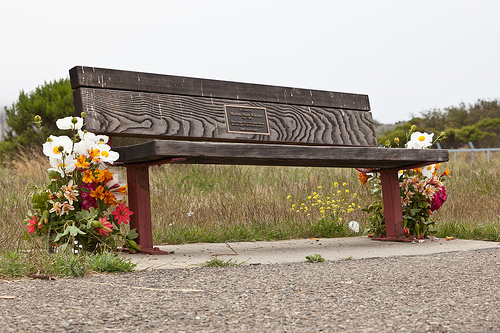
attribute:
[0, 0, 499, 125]
sky — clear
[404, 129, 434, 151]
flower — white, yellow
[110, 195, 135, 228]
flower — red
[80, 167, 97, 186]
flower — orange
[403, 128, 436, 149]
flower — yellow, white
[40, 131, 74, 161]
flower — white, yellow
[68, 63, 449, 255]
bench — vacant, wooden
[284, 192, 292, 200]
flower — yellow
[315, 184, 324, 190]
flower — yellow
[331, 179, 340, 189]
flower — yellow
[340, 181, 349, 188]
flower — yellow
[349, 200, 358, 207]
flower — yellow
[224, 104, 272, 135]
plaque — brass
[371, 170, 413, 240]
leg — metal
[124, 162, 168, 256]
leg — metal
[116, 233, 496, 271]
pad — concrete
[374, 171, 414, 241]
support — red, iron, metal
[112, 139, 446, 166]
seat — wooden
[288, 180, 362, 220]
flowers — yellow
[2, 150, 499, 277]
grass — wild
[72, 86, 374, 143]
slat — wooden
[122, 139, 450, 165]
slat — wooden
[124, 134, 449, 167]
slat — wooden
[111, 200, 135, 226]
flower — red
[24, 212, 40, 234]
flower — red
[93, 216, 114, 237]
flower — red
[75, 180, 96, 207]
flower — red